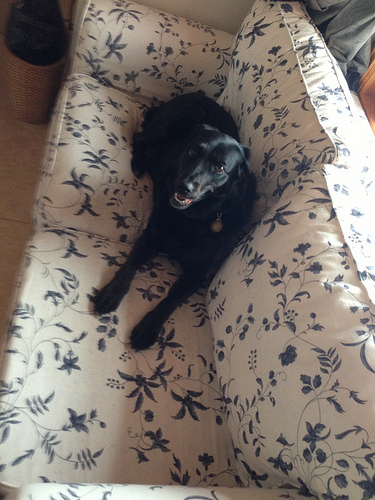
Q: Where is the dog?
A: On couch.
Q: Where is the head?
A: On dog.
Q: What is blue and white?
A: Couch.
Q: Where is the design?
A: On couch.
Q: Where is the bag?
A: In basket.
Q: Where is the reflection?
A: On cushion.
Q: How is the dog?
A: Reclined.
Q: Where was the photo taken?
A: In a living room.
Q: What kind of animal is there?
A: A dog.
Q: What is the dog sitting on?
A: A couch.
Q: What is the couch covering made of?
A: Fabric.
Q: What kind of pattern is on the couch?
A: Floral.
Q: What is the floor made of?
A: Carpet.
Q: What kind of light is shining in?
A: Sunlight.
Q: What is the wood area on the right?
A: A window frame.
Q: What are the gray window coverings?
A: Curtains.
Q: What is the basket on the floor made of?
A: Wicker.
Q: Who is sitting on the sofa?
A: A black dog.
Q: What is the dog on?
A: A couch.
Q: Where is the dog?
A: On the couch.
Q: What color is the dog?
A: Black.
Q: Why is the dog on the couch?
A: He's laying down.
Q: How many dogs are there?
A: One.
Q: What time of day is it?
A: Afternoon.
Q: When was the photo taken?
A: Daytime.